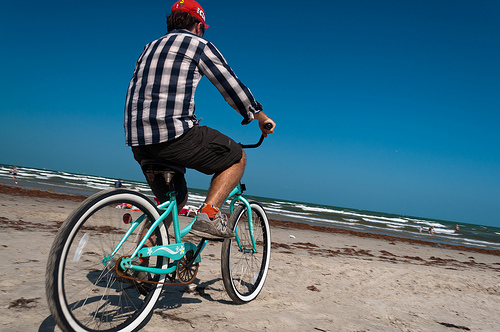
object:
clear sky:
[0, 0, 500, 228]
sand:
[271, 252, 498, 332]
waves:
[4, 165, 457, 236]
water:
[2, 162, 499, 252]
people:
[454, 224, 462, 240]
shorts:
[125, 124, 245, 203]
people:
[5, 163, 26, 184]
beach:
[0, 182, 500, 332]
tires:
[43, 188, 169, 332]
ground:
[0, 183, 500, 332]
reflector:
[71, 229, 97, 263]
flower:
[174, 240, 189, 257]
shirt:
[122, 29, 264, 150]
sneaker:
[121, 254, 157, 283]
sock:
[202, 201, 219, 221]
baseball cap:
[165, 0, 209, 27]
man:
[120, 0, 276, 240]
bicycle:
[44, 121, 273, 332]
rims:
[64, 220, 80, 249]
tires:
[218, 199, 271, 305]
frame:
[166, 209, 178, 233]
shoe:
[191, 203, 235, 241]